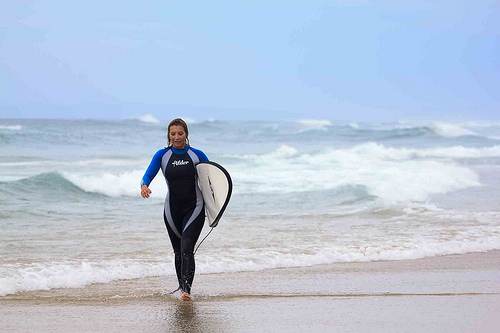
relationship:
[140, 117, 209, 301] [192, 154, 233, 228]
woman carrying surfboard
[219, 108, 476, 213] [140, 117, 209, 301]
waves behind woman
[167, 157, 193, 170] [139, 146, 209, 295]
print visible on top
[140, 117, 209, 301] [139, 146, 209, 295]
woman wearing top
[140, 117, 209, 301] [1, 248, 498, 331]
woman walking on beach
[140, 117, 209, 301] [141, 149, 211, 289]
woman wearing wet suit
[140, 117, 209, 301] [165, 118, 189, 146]
woman with hair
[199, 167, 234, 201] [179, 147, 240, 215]
logo on surfboard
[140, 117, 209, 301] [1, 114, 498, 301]
woman in ocean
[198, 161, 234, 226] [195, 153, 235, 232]
edge of surf board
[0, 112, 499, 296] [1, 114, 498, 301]
water in ocean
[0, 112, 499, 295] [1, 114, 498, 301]
waves in ocean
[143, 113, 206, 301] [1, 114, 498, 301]
woman walking out of ocean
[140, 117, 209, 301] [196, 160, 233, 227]
woman has surfboard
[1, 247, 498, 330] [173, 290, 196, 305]
sand under feet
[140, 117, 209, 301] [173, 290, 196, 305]
woman has feet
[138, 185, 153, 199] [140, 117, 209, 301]
hand of woman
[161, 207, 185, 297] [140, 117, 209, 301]
legs of woman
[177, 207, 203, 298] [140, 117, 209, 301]
legs of woman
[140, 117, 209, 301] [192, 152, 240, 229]
woman holding surfboard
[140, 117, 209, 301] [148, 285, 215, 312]
woman on sand